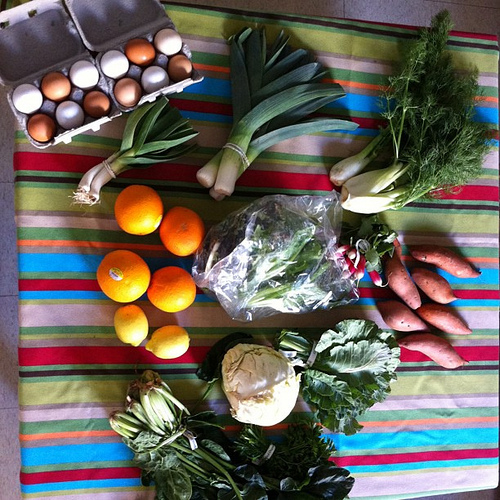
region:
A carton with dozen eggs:
[2, 0, 204, 148]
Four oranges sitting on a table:
[96, 184, 205, 311]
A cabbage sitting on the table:
[219, 342, 299, 424]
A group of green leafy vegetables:
[106, 317, 401, 499]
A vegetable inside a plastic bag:
[191, 191, 396, 323]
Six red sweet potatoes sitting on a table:
[373, 243, 483, 370]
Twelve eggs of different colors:
[11, 27, 194, 142]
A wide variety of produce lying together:
[77, 8, 496, 498]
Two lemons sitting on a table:
[113, 304, 189, 359]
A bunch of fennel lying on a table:
[332, 7, 496, 212]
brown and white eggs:
[7, 32, 193, 140]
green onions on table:
[73, 101, 194, 206]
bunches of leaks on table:
[196, 26, 359, 202]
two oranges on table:
[115, 184, 205, 257]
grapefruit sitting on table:
[95, 251, 150, 302]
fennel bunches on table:
[329, 11, 491, 213]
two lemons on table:
[113, 305, 189, 359]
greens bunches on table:
[106, 371, 266, 498]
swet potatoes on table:
[379, 241, 481, 368]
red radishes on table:
[338, 222, 393, 294]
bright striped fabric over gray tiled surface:
[2, 0, 497, 495]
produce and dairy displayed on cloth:
[1, 5, 491, 495]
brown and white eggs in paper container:
[1, 5, 208, 146]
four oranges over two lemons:
[95, 182, 198, 358]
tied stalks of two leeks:
[66, 15, 357, 199]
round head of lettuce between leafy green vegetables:
[100, 315, 390, 485]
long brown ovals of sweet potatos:
[366, 226, 476, 371]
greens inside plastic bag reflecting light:
[192, 181, 357, 321]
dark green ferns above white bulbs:
[331, 5, 491, 220]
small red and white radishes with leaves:
[332, 223, 392, 293]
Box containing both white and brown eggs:
[0, 0, 205, 151]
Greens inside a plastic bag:
[189, 187, 360, 324]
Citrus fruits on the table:
[96, 182, 203, 359]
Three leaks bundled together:
[195, 15, 360, 202]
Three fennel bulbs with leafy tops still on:
[328, 5, 498, 215]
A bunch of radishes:
[331, 230, 398, 295]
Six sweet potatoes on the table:
[381, 241, 482, 371]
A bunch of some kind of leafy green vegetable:
[275, 315, 404, 437]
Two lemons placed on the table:
[112, 301, 191, 361]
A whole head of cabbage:
[218, 340, 303, 427]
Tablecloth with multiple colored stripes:
[25, 219, 92, 499]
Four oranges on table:
[102, 195, 202, 303]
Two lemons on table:
[109, 311, 195, 360]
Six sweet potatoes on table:
[392, 236, 467, 363]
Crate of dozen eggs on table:
[10, 0, 196, 135]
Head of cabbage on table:
[220, 345, 293, 421]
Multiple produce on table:
[10, 65, 487, 499]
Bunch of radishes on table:
[333, 242, 380, 289]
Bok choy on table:
[330, 67, 482, 215]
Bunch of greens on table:
[109, 365, 229, 498]